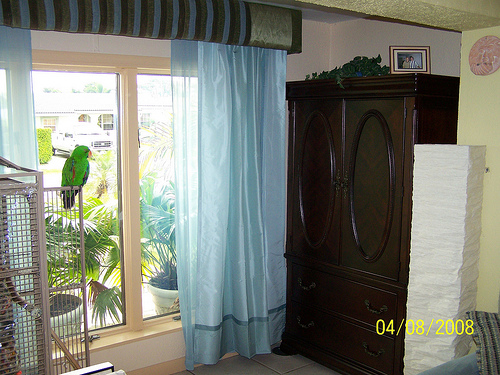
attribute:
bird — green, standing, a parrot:
[56, 145, 94, 209]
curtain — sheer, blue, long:
[171, 38, 289, 372]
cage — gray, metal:
[0, 155, 90, 374]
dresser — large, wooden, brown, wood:
[278, 70, 462, 374]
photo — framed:
[391, 44, 433, 76]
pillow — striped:
[462, 310, 499, 375]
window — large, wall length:
[1, 47, 267, 350]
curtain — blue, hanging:
[0, 25, 42, 374]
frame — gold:
[387, 44, 434, 75]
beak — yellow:
[87, 148, 94, 160]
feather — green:
[74, 158, 87, 188]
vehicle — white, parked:
[51, 118, 117, 160]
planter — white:
[50, 289, 84, 340]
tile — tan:
[240, 352, 318, 375]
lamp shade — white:
[400, 142, 488, 373]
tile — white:
[184, 354, 282, 375]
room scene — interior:
[0, 0, 499, 374]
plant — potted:
[138, 172, 225, 320]